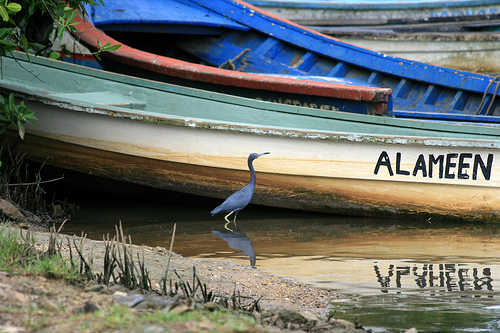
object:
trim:
[61, 5, 390, 111]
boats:
[0, 0, 500, 225]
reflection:
[214, 227, 260, 266]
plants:
[88, 219, 148, 288]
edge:
[157, 69, 399, 101]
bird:
[211, 152, 272, 232]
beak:
[258, 151, 271, 157]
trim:
[0, 45, 499, 156]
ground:
[0, 191, 500, 333]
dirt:
[0, 228, 312, 333]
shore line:
[0, 287, 332, 320]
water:
[1, 174, 498, 329]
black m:
[428, 154, 445, 178]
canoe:
[54, 0, 500, 121]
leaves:
[0, 0, 77, 40]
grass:
[2, 225, 64, 274]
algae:
[300, 193, 373, 213]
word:
[395, 150, 411, 176]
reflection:
[370, 252, 499, 301]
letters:
[375, 151, 394, 175]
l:
[394, 151, 411, 176]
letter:
[471, 153, 492, 182]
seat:
[50, 91, 146, 110]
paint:
[310, 134, 496, 146]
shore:
[5, 222, 373, 332]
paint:
[132, 51, 383, 101]